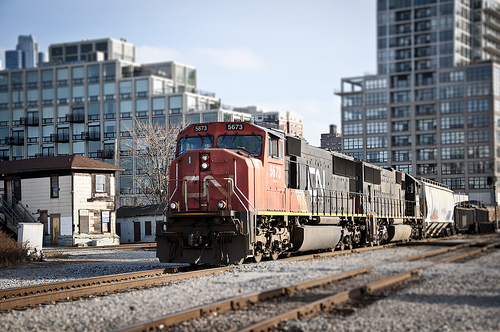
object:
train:
[153, 120, 454, 265]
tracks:
[0, 266, 168, 310]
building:
[0, 0, 498, 251]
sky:
[0, 1, 382, 147]